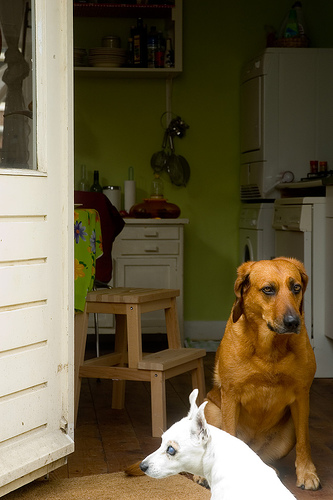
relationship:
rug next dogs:
[39, 466, 192, 498] [136, 244, 323, 498]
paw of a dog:
[292, 454, 321, 490] [200, 253, 321, 492]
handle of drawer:
[144, 228, 157, 240] [120, 224, 181, 239]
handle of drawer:
[142, 243, 158, 250] [119, 241, 182, 256]